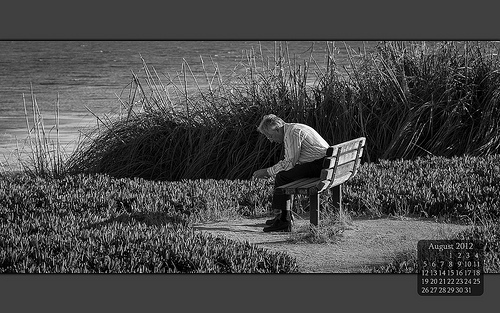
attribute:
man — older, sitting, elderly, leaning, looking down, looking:
[249, 112, 334, 238]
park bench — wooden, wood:
[274, 133, 371, 237]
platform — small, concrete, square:
[190, 201, 492, 273]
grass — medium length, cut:
[3, 154, 500, 272]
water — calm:
[0, 39, 499, 173]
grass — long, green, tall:
[13, 32, 500, 175]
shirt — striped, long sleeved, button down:
[266, 120, 332, 177]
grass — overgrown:
[282, 194, 357, 246]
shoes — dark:
[260, 213, 295, 236]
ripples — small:
[31, 73, 113, 90]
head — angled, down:
[255, 109, 286, 148]